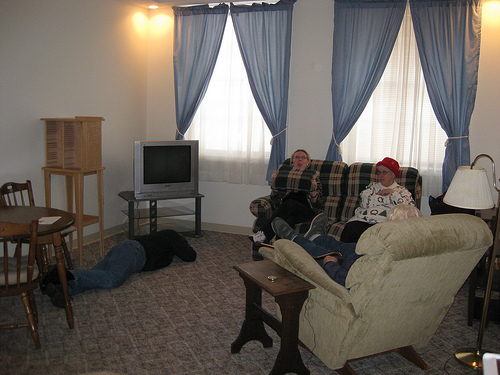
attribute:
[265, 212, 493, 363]
recliner — tan, colored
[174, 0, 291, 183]
curtain — blue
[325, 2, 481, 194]
curtain — blue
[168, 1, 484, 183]
curtains — blue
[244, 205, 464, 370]
rocking chair — tan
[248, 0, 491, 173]
chair — tan, plush, recliner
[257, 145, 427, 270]
couch — green, striped, plaid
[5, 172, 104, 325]
table — wooden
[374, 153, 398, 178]
hat — red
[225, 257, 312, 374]
table — brown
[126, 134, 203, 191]
tv screen — off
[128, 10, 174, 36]
lights — on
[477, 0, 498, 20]
lights — on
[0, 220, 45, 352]
chair — wooden, brown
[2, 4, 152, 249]
wall — white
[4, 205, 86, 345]
table — brown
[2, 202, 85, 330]
table — wooden, dark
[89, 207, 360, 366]
table — brown, wooden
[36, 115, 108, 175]
box — brown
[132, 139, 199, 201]
tv — grey, flat screen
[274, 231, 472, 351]
chair — brown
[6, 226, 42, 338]
chair — brown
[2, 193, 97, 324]
table — wood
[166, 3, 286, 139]
curtain — blue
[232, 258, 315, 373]
side table — small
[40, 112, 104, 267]
cabinet — tan, wooden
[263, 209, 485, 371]
recliner — beige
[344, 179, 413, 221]
sweater — white